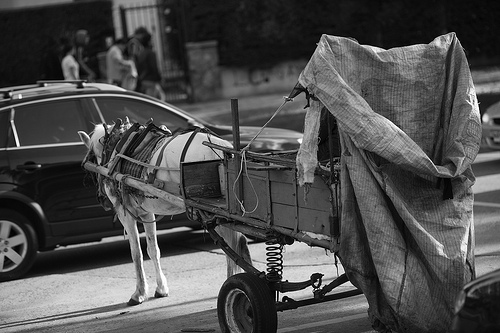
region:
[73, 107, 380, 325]
Horse pulling small cart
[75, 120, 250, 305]
Small white horse or pony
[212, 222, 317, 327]
Wheel with spring suspension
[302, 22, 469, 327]
Bag attached to back of cart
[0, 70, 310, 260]
Dark colored car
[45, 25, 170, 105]
Group of people walking on the sidewalk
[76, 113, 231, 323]
Horse standing in the street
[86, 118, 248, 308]
Horse in a harness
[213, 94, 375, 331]
Small 2-wheel cart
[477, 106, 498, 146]
Lit headlight of a car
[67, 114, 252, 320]
bowed white horse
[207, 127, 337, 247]
wooden horse drawn cart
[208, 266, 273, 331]
black rubber cart tire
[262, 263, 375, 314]
metal wheel axle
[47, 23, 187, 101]
group of people walking down the street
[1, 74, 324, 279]
shiny newer looking car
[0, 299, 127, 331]
long shadow of horses legs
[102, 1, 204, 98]
black metal gate way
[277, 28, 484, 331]
canvass bag tied to a horse cart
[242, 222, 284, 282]
makeshift metal spring shocks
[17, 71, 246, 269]
the car is black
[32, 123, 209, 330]
the car is black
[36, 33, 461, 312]
The picture is black and white.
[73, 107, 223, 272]
The horse is carrying a buggy.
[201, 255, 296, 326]
the wheel on the buggy.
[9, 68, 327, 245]
The car is in front of the horse.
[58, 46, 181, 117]
People walking on the sidewalk.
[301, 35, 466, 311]
A bag over the buggy.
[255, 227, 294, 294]
Springs under the buggy.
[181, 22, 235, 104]
A garbage can on the sidewalk.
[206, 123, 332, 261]
The buggy is made of wood and sticks.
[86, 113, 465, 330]
The horse and buggy is on the street.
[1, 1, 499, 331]
the photo is black and white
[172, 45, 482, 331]
the horse has a cart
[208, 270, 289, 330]
the cart has a black wheel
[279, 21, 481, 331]
the cart has a large bag on it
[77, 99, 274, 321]
the horse is standing on the road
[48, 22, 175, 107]
the people are on the other side of the road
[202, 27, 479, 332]
the cart is old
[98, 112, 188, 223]
the harness is bulky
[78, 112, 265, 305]
the horse is light